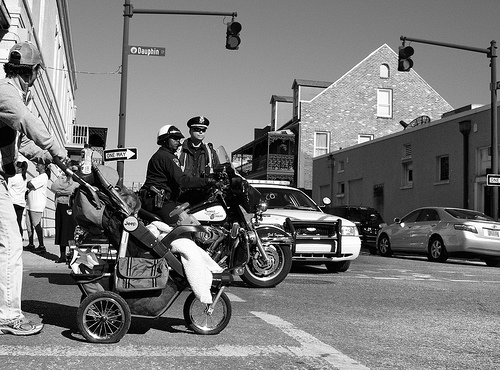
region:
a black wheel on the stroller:
[177, 284, 234, 337]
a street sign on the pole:
[121, 42, 168, 60]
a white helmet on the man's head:
[154, 122, 186, 142]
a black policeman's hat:
[185, 112, 210, 130]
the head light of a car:
[333, 223, 364, 240]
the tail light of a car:
[449, 222, 478, 234]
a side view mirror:
[390, 212, 405, 227]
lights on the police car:
[240, 176, 294, 186]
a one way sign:
[97, 144, 141, 165]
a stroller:
[43, 138, 245, 343]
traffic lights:
[94, 6, 498, 201]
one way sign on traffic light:
[99, 143, 140, 168]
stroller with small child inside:
[51, 152, 245, 343]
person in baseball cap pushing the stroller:
[1, 40, 70, 346]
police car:
[220, 173, 365, 276]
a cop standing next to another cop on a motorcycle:
[133, 109, 220, 228]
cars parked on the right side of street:
[317, 196, 495, 268]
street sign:
[119, 39, 167, 61]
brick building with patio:
[230, 39, 460, 195]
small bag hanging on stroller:
[98, 247, 173, 294]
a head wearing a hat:
[185, 112, 210, 146]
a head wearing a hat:
[154, 119, 182, 152]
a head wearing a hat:
[6, 37, 42, 77]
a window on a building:
[398, 152, 415, 187]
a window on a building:
[433, 153, 450, 181]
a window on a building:
[335, 177, 345, 192]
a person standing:
[27, 155, 52, 250]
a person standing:
[8, 156, 28, 247]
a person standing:
[1, 37, 77, 347]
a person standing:
[180, 110, 229, 184]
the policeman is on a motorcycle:
[153, 102, 288, 303]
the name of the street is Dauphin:
[121, 28, 187, 66]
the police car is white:
[250, 166, 365, 280]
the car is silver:
[371, 194, 498, 266]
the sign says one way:
[92, 134, 136, 166]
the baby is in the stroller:
[39, 146, 254, 349]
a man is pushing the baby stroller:
[5, 35, 206, 346]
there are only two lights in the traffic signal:
[206, 2, 269, 60]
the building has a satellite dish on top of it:
[401, 97, 433, 136]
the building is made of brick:
[343, 42, 453, 137]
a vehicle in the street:
[369, 202, 497, 263]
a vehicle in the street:
[226, 164, 363, 288]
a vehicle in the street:
[321, 190, 379, 247]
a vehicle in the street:
[63, 148, 241, 349]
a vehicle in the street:
[179, 170, 292, 296]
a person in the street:
[178, 109, 222, 187]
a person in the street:
[131, 120, 196, 208]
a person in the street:
[0, 42, 78, 344]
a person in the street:
[48, 146, 81, 251]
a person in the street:
[21, 153, 53, 262]